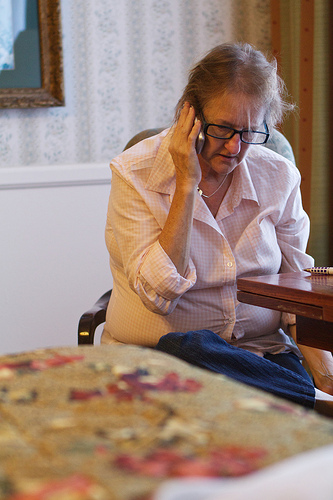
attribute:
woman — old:
[99, 43, 332, 418]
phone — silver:
[183, 102, 205, 155]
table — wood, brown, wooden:
[235, 266, 333, 325]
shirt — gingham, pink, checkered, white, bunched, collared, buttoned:
[100, 123, 315, 356]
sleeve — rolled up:
[106, 158, 199, 316]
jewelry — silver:
[197, 174, 229, 199]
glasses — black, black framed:
[193, 96, 271, 147]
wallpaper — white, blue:
[2, 1, 274, 167]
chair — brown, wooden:
[79, 126, 296, 347]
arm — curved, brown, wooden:
[79, 287, 113, 345]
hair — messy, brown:
[170, 41, 299, 144]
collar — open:
[146, 119, 261, 238]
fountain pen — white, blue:
[303, 267, 331, 277]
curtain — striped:
[271, 0, 333, 268]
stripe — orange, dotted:
[299, 2, 315, 216]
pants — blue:
[157, 328, 317, 408]